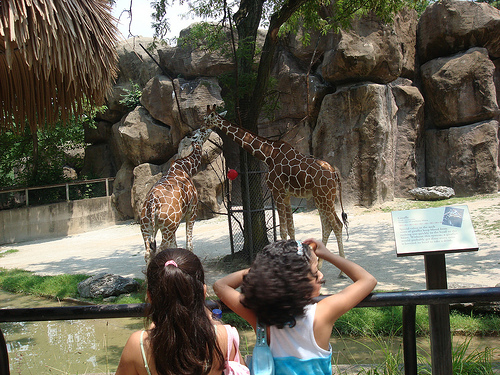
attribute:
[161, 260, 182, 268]
hair tie — pink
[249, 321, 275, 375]
purse — blue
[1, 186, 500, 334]
ground — smooth, white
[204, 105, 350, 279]
giraffe — in the zoo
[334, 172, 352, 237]
tail — black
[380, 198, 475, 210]
grass — short, green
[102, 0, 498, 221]
rocks — big, large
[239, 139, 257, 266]
pole — metal, black, thick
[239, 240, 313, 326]
hair — black, curly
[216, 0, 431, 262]
tree — dark green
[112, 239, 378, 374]
girls — little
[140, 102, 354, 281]
giraffes — standing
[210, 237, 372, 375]
girl — little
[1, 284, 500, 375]
fence — black, metal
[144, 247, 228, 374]
hair — dark, in a ponytail, pulled back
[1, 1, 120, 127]
palm fonds — dead, brown, dry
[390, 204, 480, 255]
sign — inside the enclosure, informative, grey, white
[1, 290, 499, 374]
water — muddy, brown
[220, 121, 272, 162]
neck — long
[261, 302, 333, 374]
dress — blue, white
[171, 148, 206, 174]
neck — bent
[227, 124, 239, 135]
spot — brown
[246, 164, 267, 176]
bar — grey, metal